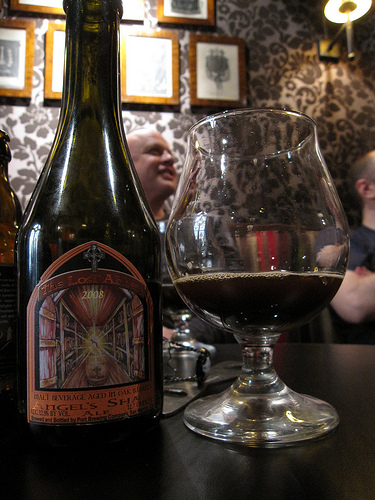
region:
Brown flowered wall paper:
[255, 17, 312, 99]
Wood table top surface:
[47, 443, 218, 486]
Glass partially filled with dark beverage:
[187, 129, 335, 453]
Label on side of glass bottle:
[26, 227, 159, 435]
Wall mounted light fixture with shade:
[310, 2, 373, 67]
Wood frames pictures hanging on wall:
[128, 3, 253, 112]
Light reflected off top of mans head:
[121, 123, 160, 141]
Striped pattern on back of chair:
[248, 228, 316, 259]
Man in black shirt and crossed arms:
[340, 140, 373, 336]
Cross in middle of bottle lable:
[90, 362, 107, 383]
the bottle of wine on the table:
[15, 1, 153, 433]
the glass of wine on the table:
[152, 95, 347, 447]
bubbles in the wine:
[173, 271, 287, 282]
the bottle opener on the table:
[159, 345, 258, 416]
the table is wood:
[2, 345, 371, 490]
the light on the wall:
[317, 3, 373, 72]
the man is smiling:
[118, 117, 185, 214]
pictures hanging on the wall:
[4, 0, 263, 107]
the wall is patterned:
[256, 20, 372, 128]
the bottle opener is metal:
[150, 354, 259, 422]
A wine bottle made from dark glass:
[10, 6, 169, 492]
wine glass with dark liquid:
[165, 105, 350, 464]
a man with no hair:
[126, 120, 181, 208]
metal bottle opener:
[160, 350, 254, 416]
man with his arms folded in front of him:
[324, 145, 373, 340]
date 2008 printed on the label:
[79, 289, 109, 303]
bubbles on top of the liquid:
[175, 268, 305, 285]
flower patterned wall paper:
[255, 27, 310, 100]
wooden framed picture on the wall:
[184, 27, 252, 115]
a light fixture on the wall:
[313, 4, 361, 82]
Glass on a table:
[168, 114, 359, 459]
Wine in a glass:
[163, 210, 366, 351]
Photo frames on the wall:
[7, 0, 256, 123]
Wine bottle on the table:
[21, 10, 169, 440]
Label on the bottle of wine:
[12, 244, 175, 435]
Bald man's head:
[110, 122, 192, 216]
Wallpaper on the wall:
[251, 7, 315, 99]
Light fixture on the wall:
[300, 0, 372, 81]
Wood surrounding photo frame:
[182, 30, 255, 117]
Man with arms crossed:
[305, 146, 374, 335]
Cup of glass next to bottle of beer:
[164, 105, 354, 446]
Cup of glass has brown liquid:
[169, 107, 349, 447]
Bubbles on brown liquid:
[172, 268, 287, 283]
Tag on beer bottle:
[24, 238, 159, 426]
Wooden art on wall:
[120, 30, 179, 106]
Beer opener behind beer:
[156, 350, 244, 419]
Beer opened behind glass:
[158, 353, 247, 421]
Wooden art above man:
[120, 26, 181, 109]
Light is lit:
[313, 0, 373, 65]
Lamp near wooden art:
[318, 0, 371, 62]